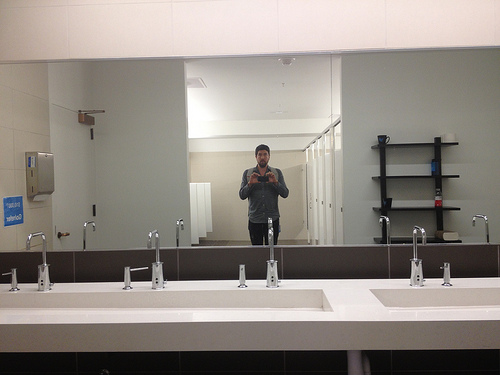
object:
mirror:
[0, 47, 500, 254]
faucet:
[27, 232, 54, 290]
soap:
[1, 266, 18, 291]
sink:
[0, 287, 333, 310]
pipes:
[437, 259, 452, 287]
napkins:
[23, 148, 54, 205]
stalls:
[294, 132, 346, 242]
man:
[238, 143, 292, 247]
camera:
[257, 174, 272, 183]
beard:
[258, 160, 267, 166]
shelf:
[370, 139, 461, 151]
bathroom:
[0, 0, 500, 374]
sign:
[2, 193, 28, 228]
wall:
[2, 61, 94, 261]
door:
[304, 153, 314, 244]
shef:
[366, 134, 464, 245]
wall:
[344, 50, 500, 247]